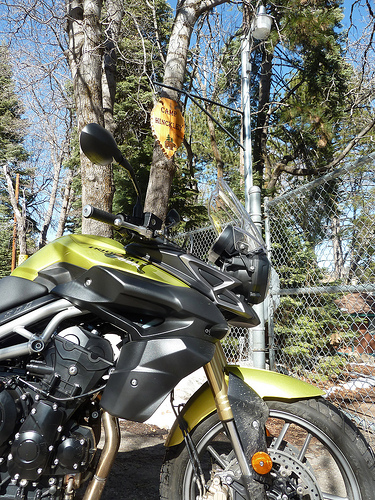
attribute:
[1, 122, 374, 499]
motorcycle — yellow, black, green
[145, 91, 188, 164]
sign — yellow, hanging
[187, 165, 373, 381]
fence — gray, wired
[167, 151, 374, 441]
fence — metal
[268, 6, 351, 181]
leaves — green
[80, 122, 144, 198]
mirror — black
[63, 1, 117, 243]
trees — tall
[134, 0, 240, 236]
trees — tall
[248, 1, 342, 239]
trees — tall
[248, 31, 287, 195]
tree — some 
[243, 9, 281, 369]
lamp post — lamp , background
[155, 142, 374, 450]
motorcycle — parked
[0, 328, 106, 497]
engine — black